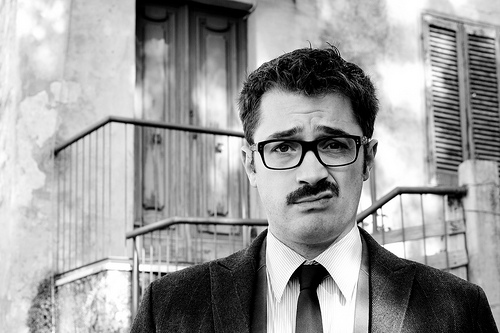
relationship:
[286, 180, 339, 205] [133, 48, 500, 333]
man`s moustache of he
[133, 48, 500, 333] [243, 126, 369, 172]
he has glasses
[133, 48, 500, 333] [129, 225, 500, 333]
he has coat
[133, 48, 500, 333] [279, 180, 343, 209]
he has mustache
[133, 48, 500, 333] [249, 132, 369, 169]
he wearing black glasses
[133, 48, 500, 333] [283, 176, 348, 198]
he has hair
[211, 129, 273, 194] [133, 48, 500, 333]
ear of he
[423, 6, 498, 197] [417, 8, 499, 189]
shutters over window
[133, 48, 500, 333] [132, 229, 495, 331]
he wearing suit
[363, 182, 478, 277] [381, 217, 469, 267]
railing by stairs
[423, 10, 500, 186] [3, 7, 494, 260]
shutters on building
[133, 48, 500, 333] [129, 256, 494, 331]
he in coat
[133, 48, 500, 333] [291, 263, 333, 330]
he in tie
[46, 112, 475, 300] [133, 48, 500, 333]
railings behind he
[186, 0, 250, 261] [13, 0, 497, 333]
door on building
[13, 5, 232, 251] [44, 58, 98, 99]
building has part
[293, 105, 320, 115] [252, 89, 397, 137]
line on forehead